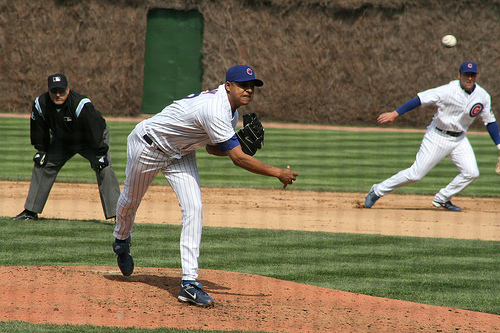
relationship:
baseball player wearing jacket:
[7, 74, 133, 234] [20, 97, 95, 159]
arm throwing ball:
[208, 102, 297, 180] [442, 32, 455, 47]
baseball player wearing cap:
[365, 62, 500, 212] [456, 59, 477, 73]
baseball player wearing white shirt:
[365, 62, 500, 212] [363, 69, 495, 214]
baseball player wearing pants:
[112, 64, 298, 306] [371, 126, 483, 198]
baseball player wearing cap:
[112, 64, 298, 306] [217, 61, 290, 92]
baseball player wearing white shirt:
[112, 64, 298, 306] [139, 82, 246, 159]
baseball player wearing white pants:
[112, 64, 298, 306] [109, 120, 205, 283]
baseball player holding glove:
[112, 64, 298, 306] [234, 110, 266, 155]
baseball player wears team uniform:
[365, 62, 500, 212] [375, 79, 493, 197]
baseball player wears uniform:
[112, 64, 298, 306] [110, 79, 243, 278]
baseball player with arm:
[112, 64, 298, 306] [207, 100, 299, 190]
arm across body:
[207, 100, 299, 190] [119, 89, 231, 306]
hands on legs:
[92, 157, 104, 165] [90, 155, 121, 211]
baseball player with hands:
[7, 74, 133, 234] [92, 157, 104, 165]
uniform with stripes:
[110, 79, 243, 278] [133, 148, 151, 182]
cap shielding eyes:
[456, 47, 488, 141] [239, 82, 260, 85]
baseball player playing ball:
[7, 74, 133, 234] [442, 35, 458, 48]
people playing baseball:
[23, 25, 492, 314] [441, 26, 457, 53]